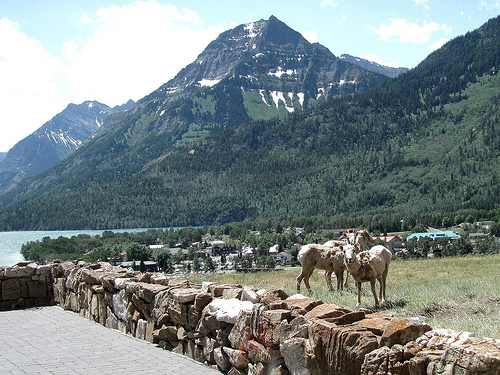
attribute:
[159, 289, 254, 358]
wall — rocky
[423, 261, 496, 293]
grass — long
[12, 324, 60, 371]
pavement — light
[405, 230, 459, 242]
roof — blue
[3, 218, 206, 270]
water — blue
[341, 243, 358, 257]
eyes — small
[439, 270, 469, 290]
grass — green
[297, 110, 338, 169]
hill — green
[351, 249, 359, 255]
sheeps eye — black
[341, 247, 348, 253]
sheeps eye — black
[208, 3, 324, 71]
peak — snowy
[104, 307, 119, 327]
stone — grey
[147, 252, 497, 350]
field — grassy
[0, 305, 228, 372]
pavement — bricked